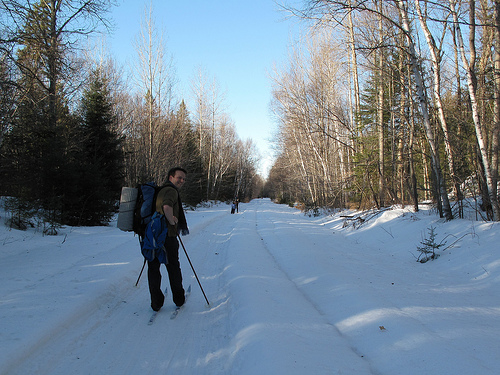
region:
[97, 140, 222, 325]
A person on skis.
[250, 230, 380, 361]
Snow on the ground.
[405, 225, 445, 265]
A little tree in the forest.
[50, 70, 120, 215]
The pine tree is green.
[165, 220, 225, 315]
The person is holding a ski pole.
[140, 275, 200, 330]
The person has a ski on each foot.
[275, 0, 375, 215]
Trees without leaves on the branches.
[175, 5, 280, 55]
The sky is light blue.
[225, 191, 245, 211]
A person in the distance.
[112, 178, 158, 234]
Gear on the person's back.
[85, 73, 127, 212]
tree along side of trail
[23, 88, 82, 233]
tree along side of trail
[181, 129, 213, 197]
tree along side of trail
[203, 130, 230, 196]
tree along side of trail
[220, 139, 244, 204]
tree along side of trail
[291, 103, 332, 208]
tree along side of trail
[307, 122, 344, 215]
tree along side of trail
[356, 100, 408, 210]
tree along side of trail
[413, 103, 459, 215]
tree along side of trail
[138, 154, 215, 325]
man cross country skiing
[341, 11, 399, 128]
brown trees in the winter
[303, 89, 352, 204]
brown trees in the winter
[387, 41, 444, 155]
brown trees in the winter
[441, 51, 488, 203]
brown trees in the winter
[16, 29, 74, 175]
brown trees in the winter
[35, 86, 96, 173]
brown trees in the winter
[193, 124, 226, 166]
brown trees in the winter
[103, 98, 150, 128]
brown trees in the winter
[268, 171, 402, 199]
brown trees in the winter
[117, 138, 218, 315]
person cross country skiing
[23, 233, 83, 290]
white snow on the ground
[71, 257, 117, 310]
white snow on the ground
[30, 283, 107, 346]
white snow on the ground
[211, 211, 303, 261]
white snow on the ground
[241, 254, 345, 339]
white snow on the ground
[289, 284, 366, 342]
white snow on the ground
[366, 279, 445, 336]
white snow on the ground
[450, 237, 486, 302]
white snow on the ground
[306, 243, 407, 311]
white snow on the ground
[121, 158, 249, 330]
man with skis on the trail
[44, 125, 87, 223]
trees on the sides of the trail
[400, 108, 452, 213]
trees on the sides of the trail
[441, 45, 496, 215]
trees on the sides of the trail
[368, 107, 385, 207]
trees on the sides of the trail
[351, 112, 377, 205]
trees on the sides of the trail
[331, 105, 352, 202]
trees on the sides of the trail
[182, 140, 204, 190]
trees on the sides of the trail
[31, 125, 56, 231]
trees on the sides of the trail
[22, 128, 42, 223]
trees on the sides of the trail